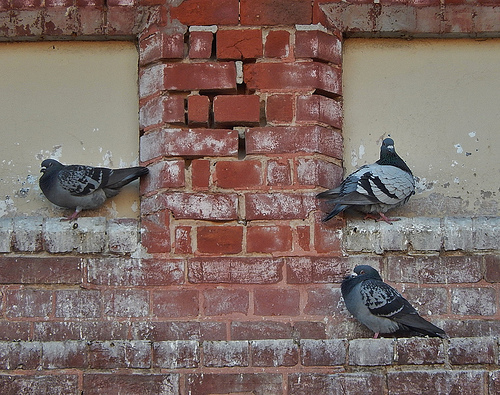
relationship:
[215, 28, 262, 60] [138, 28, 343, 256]
brick in wall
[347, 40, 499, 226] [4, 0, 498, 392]
wall on building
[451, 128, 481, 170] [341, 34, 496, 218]
chips on wall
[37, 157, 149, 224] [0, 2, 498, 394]
bird near fireplace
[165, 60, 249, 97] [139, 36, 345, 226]
brick near brick chimney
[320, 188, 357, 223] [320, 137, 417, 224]
tail feathers of bird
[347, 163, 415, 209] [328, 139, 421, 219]
wing of bird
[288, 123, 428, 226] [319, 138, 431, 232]
feathers on bird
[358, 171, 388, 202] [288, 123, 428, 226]
tips on feathers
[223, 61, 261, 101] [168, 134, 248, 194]
hole in bricks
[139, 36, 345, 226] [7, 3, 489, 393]
brick chimney on home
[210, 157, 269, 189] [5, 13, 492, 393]
brick on wall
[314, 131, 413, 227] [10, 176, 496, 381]
dove on ledge